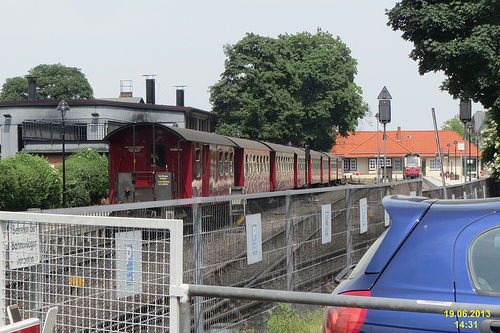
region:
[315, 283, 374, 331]
the tail light of a car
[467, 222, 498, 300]
the door window of a car door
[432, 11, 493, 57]
the leaves of a tree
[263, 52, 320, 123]
the leaves of a tree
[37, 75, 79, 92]
the leaves of a tree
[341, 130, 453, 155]
the roof of a building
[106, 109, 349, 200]
a red train on train tracks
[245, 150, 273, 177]
the windows on a train car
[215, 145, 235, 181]
the windows on a train car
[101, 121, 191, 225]
the back of a train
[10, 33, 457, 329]
The train is passing through a city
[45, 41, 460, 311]
The train is carrying passengers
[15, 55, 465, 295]
The train is going to the station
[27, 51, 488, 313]
The train is bringing people home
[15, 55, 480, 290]
A train is taking people to work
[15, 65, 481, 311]
A train is traveling on the tracks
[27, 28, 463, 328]
A train is running in the daytime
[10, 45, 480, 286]
The train has many big cars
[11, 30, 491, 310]
The train is passing some houses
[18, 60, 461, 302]
The train is run by the city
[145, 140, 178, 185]
Small window on a train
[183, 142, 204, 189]
Small window on a train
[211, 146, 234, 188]
Small window on a train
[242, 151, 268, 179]
Small window on a train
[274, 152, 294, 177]
Small window on a train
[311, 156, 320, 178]
Small window on a train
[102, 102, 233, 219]
Red train car on tracks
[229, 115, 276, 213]
Red train car on tracks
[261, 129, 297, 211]
Red train car on tracks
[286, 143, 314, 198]
Red train car on tracks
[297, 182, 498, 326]
the car is blue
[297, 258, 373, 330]
car has red tail light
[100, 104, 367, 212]
the train is red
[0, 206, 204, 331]
the fence is white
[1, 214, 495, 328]
railing attached to fence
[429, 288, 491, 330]
yellow numbers on picture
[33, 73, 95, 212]
street light next to train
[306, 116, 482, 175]
building's roof is orange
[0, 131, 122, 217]
bushes next to train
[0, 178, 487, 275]
white signs on fence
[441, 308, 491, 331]
Date and time stamp on photo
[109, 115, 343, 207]
A red passenger train.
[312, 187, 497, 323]
A blue car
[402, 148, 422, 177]
A red train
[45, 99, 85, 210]
A lamp post.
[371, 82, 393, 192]
Signal for trains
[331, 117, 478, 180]
A building with an orange roof.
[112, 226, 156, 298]
A parking sign on a fence.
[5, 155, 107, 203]
A group of bushes.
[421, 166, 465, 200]
A sidewalk along a set of railroad tracks.